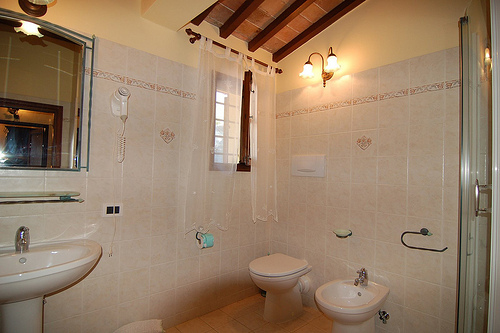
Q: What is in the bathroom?
A: Toilet.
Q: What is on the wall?
A: Mirror.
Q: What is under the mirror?
A: Sink.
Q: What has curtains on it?
A: Window.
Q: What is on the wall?
A: Tile.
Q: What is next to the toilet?
A: Toilet paper.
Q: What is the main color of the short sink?
A: White.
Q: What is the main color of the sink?
A: White.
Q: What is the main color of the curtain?
A: White.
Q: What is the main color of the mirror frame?
A: Gray.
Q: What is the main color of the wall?
A: White.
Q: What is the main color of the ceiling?
A: Brown.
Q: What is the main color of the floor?
A: Brown.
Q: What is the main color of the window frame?
A: White.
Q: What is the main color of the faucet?
A: Silver.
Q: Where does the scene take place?
A: In a bathroom.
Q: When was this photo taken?
A: Daytime.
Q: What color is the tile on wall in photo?
A: White.